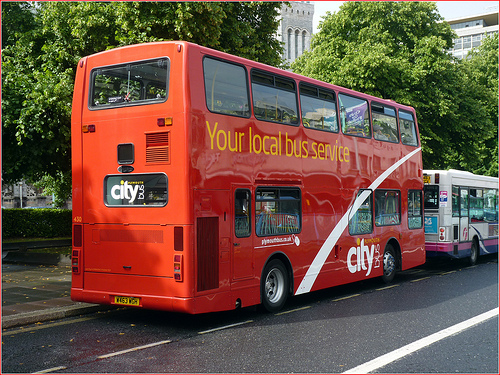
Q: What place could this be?
A: It is a road.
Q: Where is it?
A: This is at the road.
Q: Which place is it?
A: It is a road.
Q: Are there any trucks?
A: No, there are no trucks.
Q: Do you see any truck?
A: No, there are no trucks.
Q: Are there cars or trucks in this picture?
A: No, there are no trucks or cars.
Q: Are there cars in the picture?
A: No, there are no cars.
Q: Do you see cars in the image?
A: No, there are no cars.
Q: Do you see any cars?
A: No, there are no cars.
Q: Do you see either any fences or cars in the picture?
A: No, there are no cars or fences.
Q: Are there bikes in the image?
A: No, there are no bikes.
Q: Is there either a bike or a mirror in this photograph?
A: No, there are no bikes or mirrors.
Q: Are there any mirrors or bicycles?
A: No, there are no bicycles or mirrors.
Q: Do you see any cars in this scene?
A: No, there are no cars.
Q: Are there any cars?
A: No, there are no cars.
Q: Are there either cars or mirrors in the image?
A: No, there are no cars or mirrors.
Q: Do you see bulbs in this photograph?
A: No, there are no bulbs.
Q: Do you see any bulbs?
A: No, there are no bulbs.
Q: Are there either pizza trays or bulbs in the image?
A: No, there are no bulbs or pizza trays.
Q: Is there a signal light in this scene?
A: No, there are no traffic lights.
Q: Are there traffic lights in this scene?
A: No, there are no traffic lights.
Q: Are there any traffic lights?
A: No, there are no traffic lights.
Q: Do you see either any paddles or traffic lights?
A: No, there are no traffic lights or paddles.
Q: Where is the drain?
A: The drain is on the sidewalk.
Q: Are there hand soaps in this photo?
A: No, there are no hand soaps.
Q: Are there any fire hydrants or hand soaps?
A: No, there are no hand soaps or fire hydrants.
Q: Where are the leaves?
A: The leaves are on the sidewalk.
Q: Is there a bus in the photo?
A: Yes, there is a bus.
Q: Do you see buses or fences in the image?
A: Yes, there is a bus.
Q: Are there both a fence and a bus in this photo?
A: No, there is a bus but no fences.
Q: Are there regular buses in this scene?
A: Yes, there is a regular bus.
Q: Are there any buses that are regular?
A: Yes, there is a bus that is regular.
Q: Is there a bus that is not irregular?
A: Yes, there is an regular bus.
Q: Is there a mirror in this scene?
A: No, there are no mirrors.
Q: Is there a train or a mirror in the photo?
A: No, there are no mirrors or trains.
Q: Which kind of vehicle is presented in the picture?
A: The vehicle is a bus.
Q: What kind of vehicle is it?
A: The vehicle is a bus.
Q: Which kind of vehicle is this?
A: This is a bus.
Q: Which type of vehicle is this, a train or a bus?
A: This is a bus.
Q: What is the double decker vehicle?
A: The vehicle is a bus.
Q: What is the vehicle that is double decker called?
A: The vehicle is a bus.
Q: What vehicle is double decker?
A: The vehicle is a bus.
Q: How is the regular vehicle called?
A: The vehicle is a bus.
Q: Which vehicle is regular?
A: The vehicle is a bus.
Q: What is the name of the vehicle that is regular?
A: The vehicle is a bus.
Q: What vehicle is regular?
A: The vehicle is a bus.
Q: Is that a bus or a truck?
A: That is a bus.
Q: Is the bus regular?
A: Yes, the bus is regular.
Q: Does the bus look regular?
A: Yes, the bus is regular.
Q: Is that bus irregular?
A: No, the bus is regular.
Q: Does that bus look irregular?
A: No, the bus is regular.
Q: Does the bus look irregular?
A: No, the bus is regular.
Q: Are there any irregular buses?
A: No, there is a bus but it is regular.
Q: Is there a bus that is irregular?
A: No, there is a bus but it is regular.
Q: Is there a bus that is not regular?
A: No, there is a bus but it is regular.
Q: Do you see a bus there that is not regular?
A: No, there is a bus but it is regular.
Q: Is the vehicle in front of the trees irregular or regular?
A: The bus is regular.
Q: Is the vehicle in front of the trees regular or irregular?
A: The bus is regular.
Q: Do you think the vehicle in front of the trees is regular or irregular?
A: The bus is regular.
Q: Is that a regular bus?
A: Yes, that is a regular bus.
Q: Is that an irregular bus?
A: No, that is a regular bus.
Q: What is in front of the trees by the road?
A: The bus is in front of the trees.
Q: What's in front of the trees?
A: The bus is in front of the trees.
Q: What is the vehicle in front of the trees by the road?
A: The vehicle is a bus.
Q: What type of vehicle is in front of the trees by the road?
A: The vehicle is a bus.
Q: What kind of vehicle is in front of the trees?
A: The vehicle is a bus.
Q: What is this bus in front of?
A: The bus is in front of the trees.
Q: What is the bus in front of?
A: The bus is in front of the trees.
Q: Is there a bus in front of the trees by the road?
A: Yes, there is a bus in front of the trees.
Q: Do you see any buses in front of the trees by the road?
A: Yes, there is a bus in front of the trees.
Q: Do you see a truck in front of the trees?
A: No, there is a bus in front of the trees.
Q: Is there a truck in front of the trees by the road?
A: No, there is a bus in front of the trees.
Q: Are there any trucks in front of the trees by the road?
A: No, there is a bus in front of the trees.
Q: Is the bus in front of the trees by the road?
A: Yes, the bus is in front of the trees.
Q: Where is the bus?
A: The bus is on the road.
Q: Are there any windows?
A: Yes, there is a window.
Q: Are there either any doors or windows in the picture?
A: Yes, there is a window.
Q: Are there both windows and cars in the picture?
A: No, there is a window but no cars.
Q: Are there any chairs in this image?
A: No, there are no chairs.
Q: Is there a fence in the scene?
A: No, there are no fences.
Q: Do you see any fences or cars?
A: No, there are no fences or cars.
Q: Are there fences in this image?
A: No, there are no fences.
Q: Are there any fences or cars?
A: No, there are no fences or cars.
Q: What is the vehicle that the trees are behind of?
A: The vehicle is a bus.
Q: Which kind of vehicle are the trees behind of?
A: The trees are behind the bus.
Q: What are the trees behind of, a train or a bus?
A: The trees are behind a bus.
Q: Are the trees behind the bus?
A: Yes, the trees are behind the bus.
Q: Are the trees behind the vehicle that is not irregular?
A: Yes, the trees are behind the bus.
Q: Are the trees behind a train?
A: No, the trees are behind the bus.